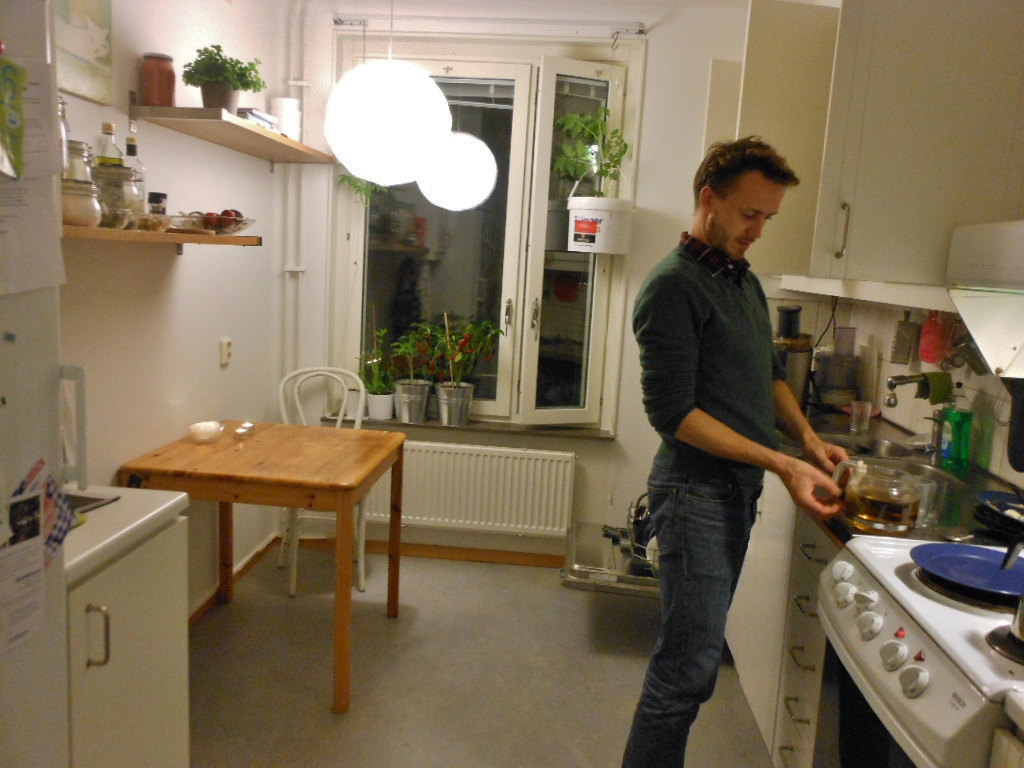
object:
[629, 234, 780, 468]
shirt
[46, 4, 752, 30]
ceiling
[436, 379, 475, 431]
tin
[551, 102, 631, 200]
plant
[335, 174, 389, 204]
plant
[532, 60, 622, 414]
window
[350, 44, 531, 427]
window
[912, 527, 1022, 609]
blue dish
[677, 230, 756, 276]
collar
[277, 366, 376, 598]
chair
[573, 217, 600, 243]
label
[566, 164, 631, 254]
pail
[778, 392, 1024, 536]
counter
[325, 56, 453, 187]
light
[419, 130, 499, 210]
light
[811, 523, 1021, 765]
stove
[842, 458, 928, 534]
pitcher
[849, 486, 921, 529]
liquid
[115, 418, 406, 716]
table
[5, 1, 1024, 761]
kitchen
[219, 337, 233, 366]
outlet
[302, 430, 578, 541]
radiator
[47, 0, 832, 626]
wall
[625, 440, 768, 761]
jeans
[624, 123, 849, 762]
man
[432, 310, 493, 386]
plant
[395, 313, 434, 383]
plant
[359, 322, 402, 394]
plant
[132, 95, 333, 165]
shelf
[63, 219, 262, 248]
shelf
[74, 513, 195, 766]
cupboard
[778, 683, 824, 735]
door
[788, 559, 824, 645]
door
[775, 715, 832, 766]
door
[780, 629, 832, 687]
door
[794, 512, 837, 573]
door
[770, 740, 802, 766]
drawer handle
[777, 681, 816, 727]
drawer handle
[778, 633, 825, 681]
drawer handle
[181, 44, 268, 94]
plant